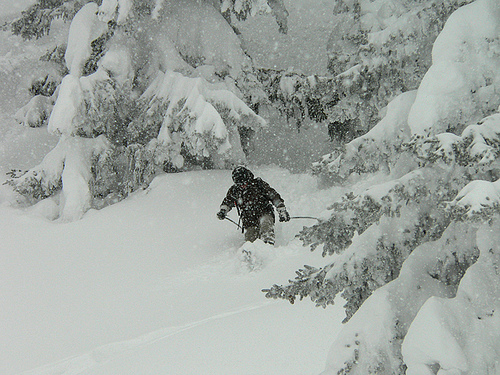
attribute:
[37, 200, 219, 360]
snow — white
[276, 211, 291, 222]
glove — black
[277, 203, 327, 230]
pole — black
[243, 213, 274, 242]
pants — grey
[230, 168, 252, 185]
goggles — black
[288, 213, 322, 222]
pole — black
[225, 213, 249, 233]
pole — black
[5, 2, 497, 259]
snow — falling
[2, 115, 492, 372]
snow — white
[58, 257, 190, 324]
snow — thick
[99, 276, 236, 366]
snow — white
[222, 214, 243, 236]
ski pole — black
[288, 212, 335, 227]
pole — black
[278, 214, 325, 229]
pole — black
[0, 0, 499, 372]
snow — white, falling, heavy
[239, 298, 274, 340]
snow — white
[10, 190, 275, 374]
snow — white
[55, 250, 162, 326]
snow — white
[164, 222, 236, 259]
snow — white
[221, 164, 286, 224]
ski jacket — black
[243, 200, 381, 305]
pants — grey